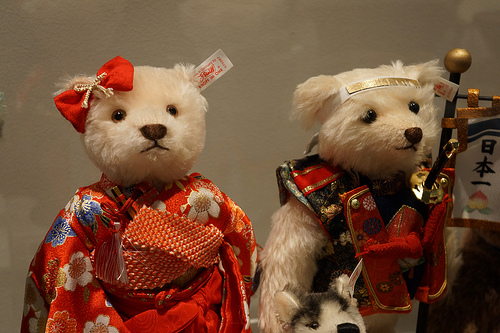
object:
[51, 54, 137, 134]
bow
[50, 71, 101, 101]
ear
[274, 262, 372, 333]
wolf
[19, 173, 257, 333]
dress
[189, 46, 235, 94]
tag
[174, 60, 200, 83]
ear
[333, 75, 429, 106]
headband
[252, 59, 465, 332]
bear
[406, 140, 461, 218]
sword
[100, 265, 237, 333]
sash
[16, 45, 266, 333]
bear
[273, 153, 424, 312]
vest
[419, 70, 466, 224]
pole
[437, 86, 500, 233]
banner